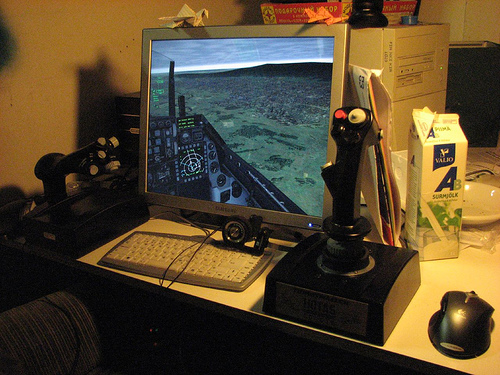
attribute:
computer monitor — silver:
[133, 25, 350, 234]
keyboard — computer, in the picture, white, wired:
[97, 221, 272, 290]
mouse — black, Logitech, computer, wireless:
[428, 283, 495, 365]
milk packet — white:
[412, 108, 463, 264]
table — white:
[15, 142, 498, 374]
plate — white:
[466, 165, 499, 225]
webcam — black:
[221, 217, 272, 250]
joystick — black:
[32, 132, 124, 187]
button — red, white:
[335, 106, 345, 119]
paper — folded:
[348, 58, 412, 251]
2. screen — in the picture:
[138, 24, 348, 238]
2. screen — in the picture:
[140, 26, 335, 222]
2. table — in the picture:
[77, 143, 490, 372]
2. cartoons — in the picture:
[147, 34, 337, 222]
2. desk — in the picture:
[78, 24, 493, 372]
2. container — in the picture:
[401, 104, 468, 261]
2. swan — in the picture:
[155, 1, 208, 31]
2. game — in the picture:
[141, 28, 334, 221]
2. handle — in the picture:
[319, 101, 383, 276]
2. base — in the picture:
[261, 231, 421, 344]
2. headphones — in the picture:
[221, 213, 271, 253]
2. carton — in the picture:
[402, 103, 469, 264]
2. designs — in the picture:
[157, 2, 347, 30]